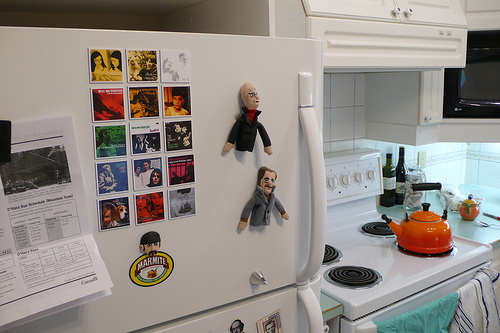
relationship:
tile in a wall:
[330, 71, 355, 112] [324, 70, 481, 216]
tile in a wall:
[470, 162, 484, 187] [327, 12, 482, 312]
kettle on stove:
[381, 181, 454, 254] [319, 147, 491, 320]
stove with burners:
[314, 137, 499, 333] [327, 209, 453, 301]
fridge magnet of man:
[221, 83, 274, 156] [225, 159, 293, 233]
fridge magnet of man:
[236, 166, 289, 230] [218, 75, 284, 160]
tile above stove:
[329, 100, 358, 140] [314, 137, 499, 333]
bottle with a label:
[395, 146, 407, 205] [393, 177, 410, 200]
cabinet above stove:
[276, 3, 489, 70] [322, 153, 497, 318]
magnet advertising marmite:
[125, 230, 182, 285] [129, 251, 169, 272]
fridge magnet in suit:
[221, 83, 274, 156] [225, 104, 272, 160]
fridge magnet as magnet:
[221, 83, 274, 156] [224, 75, 278, 162]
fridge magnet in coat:
[236, 166, 289, 230] [241, 185, 286, 226]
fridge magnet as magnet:
[236, 166, 289, 230] [246, 166, 296, 249]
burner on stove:
[330, 252, 380, 290] [319, 147, 491, 320]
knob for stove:
[333, 163, 353, 195] [326, 140, 495, 330]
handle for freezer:
[293, 69, 339, 290] [1, 24, 330, 333]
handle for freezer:
[295, 260, 335, 331] [1, 24, 330, 333]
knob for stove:
[367, 169, 377, 186] [319, 147, 491, 320]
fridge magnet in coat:
[236, 166, 289, 230] [250, 185, 286, 230]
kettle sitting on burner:
[381, 181, 454, 254] [399, 240, 453, 263]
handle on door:
[293, 72, 327, 288] [0, 20, 336, 322]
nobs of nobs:
[327, 169, 379, 188] [327, 167, 387, 191]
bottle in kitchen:
[395, 146, 407, 205] [7, 7, 477, 327]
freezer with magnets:
[1, 24, 330, 333] [69, 40, 300, 293]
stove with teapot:
[319, 147, 491, 320] [374, 165, 461, 273]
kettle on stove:
[389, 174, 458, 269] [319, 147, 491, 320]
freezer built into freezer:
[1, 24, 330, 329] [1, 24, 330, 333]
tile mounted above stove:
[353, 71, 363, 106] [319, 147, 491, 320]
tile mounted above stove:
[330, 73, 355, 108] [319, 147, 491, 320]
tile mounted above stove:
[322, 72, 331, 108] [319, 147, 491, 320]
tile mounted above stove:
[331, 106, 356, 140] [319, 147, 491, 320]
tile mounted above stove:
[353, 105, 367, 137] [319, 147, 491, 320]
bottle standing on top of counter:
[380, 153, 397, 207] [348, 207, 499, 241]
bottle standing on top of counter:
[395, 145, 406, 204] [348, 207, 499, 241]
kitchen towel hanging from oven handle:
[372, 289, 459, 331] [355, 265, 484, 330]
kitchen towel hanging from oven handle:
[448, 263, 484, 329] [355, 265, 484, 330]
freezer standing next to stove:
[1, 24, 330, 333] [319, 147, 491, 320]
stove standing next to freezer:
[319, 147, 491, 320] [1, 24, 330, 333]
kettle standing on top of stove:
[381, 181, 454, 254] [319, 147, 491, 320]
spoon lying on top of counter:
[475, 218, 484, 227] [376, 183, 484, 246]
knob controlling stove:
[327, 174, 340, 189] [319, 147, 491, 320]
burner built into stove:
[323, 265, 383, 289] [319, 147, 491, 320]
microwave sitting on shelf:
[442, 30, 484, 120] [440, 115, 484, 125]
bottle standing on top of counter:
[380, 152, 398, 206] [376, 183, 484, 246]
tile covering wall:
[330, 73, 355, 108] [323, 70, 463, 188]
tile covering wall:
[331, 106, 356, 140] [323, 70, 463, 188]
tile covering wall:
[445, 152, 462, 187] [323, 70, 463, 188]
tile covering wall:
[355, 106, 367, 138] [323, 70, 463, 188]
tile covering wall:
[467, 158, 479, 185] [463, 140, 483, 185]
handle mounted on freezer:
[293, 72, 327, 288] [1, 24, 330, 329]